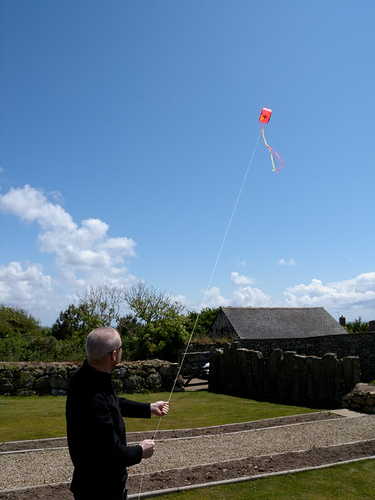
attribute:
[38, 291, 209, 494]
man — wearing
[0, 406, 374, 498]
ground — dark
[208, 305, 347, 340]
roof — gray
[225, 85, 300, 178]
kite — box style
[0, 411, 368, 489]
pathway — gravel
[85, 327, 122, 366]
hair — white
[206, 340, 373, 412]
wall — rock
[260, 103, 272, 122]
kite — airborne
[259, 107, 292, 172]
kite — green 